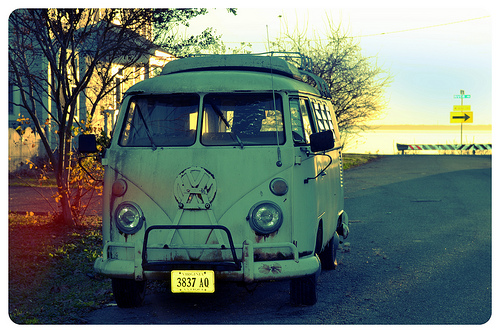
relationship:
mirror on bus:
[305, 124, 342, 156] [66, 47, 354, 307]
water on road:
[344, 124, 492, 154] [116, 149, 488, 329]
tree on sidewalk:
[9, 7, 219, 227] [8, 143, 103, 315]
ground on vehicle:
[308, 138, 405, 192] [92, 50, 348, 305]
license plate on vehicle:
[171, 270, 216, 294] [92, 50, 348, 305]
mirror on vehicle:
[154, 73, 290, 192] [62, 27, 409, 331]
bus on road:
[93, 51, 348, 308] [320, 150, 478, 320]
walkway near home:
[6, 176, 104, 222] [19, 13, 139, 140]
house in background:
[12, 12, 104, 167] [285, 39, 481, 225]